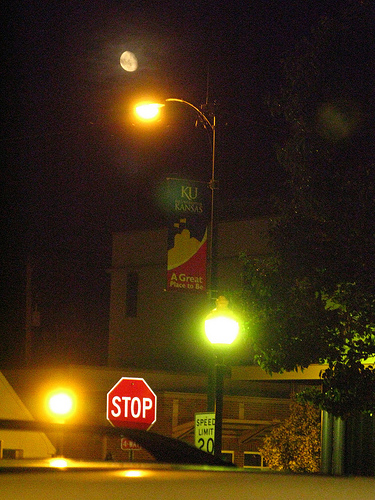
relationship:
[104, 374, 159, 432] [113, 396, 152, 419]
sign says stop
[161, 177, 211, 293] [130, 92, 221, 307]
poster on pole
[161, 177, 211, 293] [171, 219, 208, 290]
poster has advertisement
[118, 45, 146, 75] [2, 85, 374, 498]
moon over city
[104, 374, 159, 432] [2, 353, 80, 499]
sign on street corner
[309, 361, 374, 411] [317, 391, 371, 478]
plant in planter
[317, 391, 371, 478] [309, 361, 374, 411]
planter has a plant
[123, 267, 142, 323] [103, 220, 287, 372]
window on building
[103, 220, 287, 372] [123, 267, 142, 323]
building has window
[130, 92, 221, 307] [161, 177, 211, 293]
post has sign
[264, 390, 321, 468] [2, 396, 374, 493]
shrub near street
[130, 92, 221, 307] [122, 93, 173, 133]
pole has light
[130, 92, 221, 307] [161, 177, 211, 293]
pole has a poster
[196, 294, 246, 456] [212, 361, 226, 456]
lamp on pole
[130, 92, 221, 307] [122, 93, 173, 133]
pole has lamp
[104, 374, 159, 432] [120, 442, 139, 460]
sign on pole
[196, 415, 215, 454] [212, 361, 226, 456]
sign on pole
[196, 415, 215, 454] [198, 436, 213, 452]
sign has speed limit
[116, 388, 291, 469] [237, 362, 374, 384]
wall has awning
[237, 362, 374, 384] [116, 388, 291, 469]
awning on wall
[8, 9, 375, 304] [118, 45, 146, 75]
sky has moon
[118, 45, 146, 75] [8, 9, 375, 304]
moon in sky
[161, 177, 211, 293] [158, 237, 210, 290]
poster has swirl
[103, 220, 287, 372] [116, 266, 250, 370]
building has wall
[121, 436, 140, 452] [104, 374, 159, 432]
sign under stop sign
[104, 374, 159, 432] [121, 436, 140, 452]
stop sign above sign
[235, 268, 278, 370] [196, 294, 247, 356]
leaves have lamp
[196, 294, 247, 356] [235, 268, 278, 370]
lamp on leaves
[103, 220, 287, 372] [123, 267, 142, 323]
building has a window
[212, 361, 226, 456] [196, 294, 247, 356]
pole has a lamp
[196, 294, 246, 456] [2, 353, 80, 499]
lamp near street corner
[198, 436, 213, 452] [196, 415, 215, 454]
speed limit on sign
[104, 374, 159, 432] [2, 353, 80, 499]
sign near street corner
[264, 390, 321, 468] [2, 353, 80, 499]
shrub next to street corner